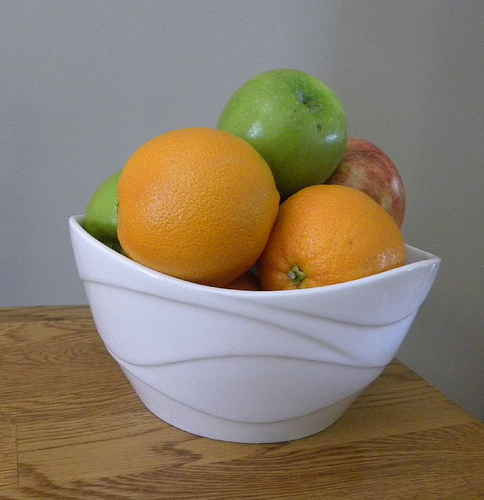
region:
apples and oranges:
[126, 59, 379, 272]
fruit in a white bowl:
[98, 58, 424, 433]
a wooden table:
[44, 407, 95, 474]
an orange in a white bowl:
[139, 113, 239, 264]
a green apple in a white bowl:
[232, 49, 323, 149]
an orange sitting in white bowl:
[135, 139, 247, 246]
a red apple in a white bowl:
[357, 135, 396, 201]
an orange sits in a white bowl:
[293, 188, 377, 273]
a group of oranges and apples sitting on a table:
[134, 66, 388, 449]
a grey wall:
[46, 21, 134, 91]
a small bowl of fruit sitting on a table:
[11, 46, 460, 492]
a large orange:
[113, 122, 274, 274]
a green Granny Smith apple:
[212, 62, 340, 183]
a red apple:
[328, 138, 401, 219]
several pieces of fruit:
[94, 64, 405, 255]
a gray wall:
[2, 6, 474, 66]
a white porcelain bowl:
[67, 278, 436, 443]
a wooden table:
[4, 311, 102, 492]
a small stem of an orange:
[284, 264, 306, 287]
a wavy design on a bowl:
[115, 288, 361, 373]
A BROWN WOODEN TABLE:
[8, 310, 161, 497]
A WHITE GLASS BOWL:
[63, 210, 448, 454]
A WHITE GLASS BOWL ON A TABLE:
[22, 251, 466, 488]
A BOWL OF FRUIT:
[56, 66, 445, 449]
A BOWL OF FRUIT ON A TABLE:
[7, 63, 479, 493]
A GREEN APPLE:
[216, 59, 356, 197]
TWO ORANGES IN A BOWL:
[113, 123, 410, 303]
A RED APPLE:
[324, 130, 438, 232]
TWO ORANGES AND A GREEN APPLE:
[114, 60, 406, 294]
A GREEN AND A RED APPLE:
[217, 65, 411, 230]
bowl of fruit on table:
[76, 64, 437, 464]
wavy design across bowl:
[50, 198, 438, 469]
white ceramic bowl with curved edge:
[60, 194, 445, 443]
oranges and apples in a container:
[80, 60, 407, 284]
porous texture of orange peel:
[111, 121, 285, 278]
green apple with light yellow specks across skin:
[214, 51, 348, 197]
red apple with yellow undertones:
[323, 118, 413, 221]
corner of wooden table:
[13, 260, 426, 491]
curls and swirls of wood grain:
[5, 312, 90, 464]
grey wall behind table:
[31, 37, 189, 121]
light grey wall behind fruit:
[6, 3, 483, 377]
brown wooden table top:
[7, 302, 478, 496]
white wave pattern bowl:
[64, 208, 442, 449]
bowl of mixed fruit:
[62, 62, 447, 443]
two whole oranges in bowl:
[114, 124, 407, 289]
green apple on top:
[219, 63, 348, 186]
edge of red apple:
[329, 135, 412, 228]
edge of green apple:
[73, 172, 131, 239]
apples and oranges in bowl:
[60, 64, 441, 451]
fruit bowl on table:
[69, 64, 443, 498]